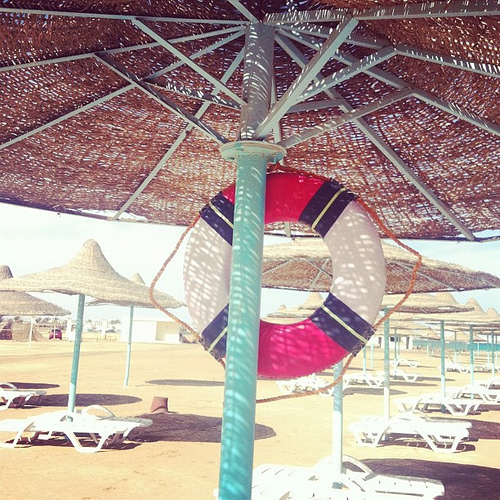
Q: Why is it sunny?
A: It is day time.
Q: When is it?
A: Day time.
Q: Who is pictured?
A: No one.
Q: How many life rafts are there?
A: One.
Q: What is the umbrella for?
A: To provide shade.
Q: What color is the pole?
A: Seagreen.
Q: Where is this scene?
A: The beach.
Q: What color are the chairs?
A: White.